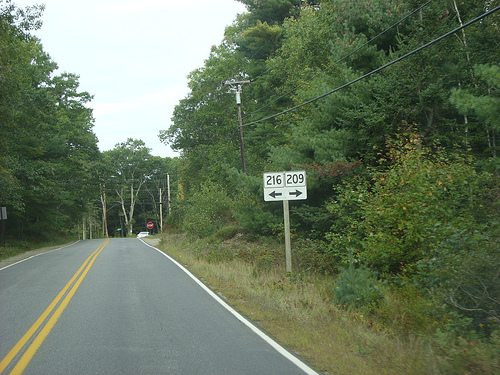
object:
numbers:
[267, 174, 305, 186]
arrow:
[268, 190, 282, 198]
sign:
[263, 171, 307, 202]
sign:
[147, 221, 155, 229]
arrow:
[289, 189, 303, 197]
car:
[136, 231, 151, 238]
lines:
[0, 236, 319, 375]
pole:
[223, 78, 252, 173]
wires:
[142, 3, 499, 197]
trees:
[0, 0, 498, 373]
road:
[1, 235, 324, 375]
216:
[267, 175, 282, 185]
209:
[287, 173, 304, 184]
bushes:
[311, 117, 500, 374]